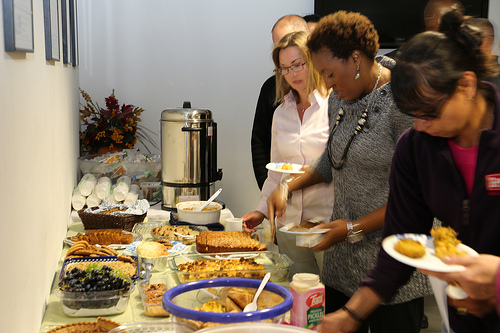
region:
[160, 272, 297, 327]
a buffet on a table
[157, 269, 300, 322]
bowl has a white spoon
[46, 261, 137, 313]
black grapes on a bowl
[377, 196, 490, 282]
a white dish with yellow food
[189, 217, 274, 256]
bread cutted in slices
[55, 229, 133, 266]
cookies behind grapes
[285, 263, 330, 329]
a bottle of souce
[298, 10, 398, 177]
woman wears a necklace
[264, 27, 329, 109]
woman wearing glasses is blonde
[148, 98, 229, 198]
a silver coffee dispenser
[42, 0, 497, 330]
people getting food at a buffet table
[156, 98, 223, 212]
coffee urn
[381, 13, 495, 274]
woman looking down with plate in hand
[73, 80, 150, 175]
flower arrangement in the corner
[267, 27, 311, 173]
blonde-haired woman with glasses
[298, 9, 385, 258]
woman wearing necklace getting some food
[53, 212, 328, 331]
variety of food on a table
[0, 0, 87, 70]
pictures on the wall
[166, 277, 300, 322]
a plastic spoon in a bowl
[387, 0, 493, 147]
woman with hair tied back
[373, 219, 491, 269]
a paper plate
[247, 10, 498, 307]
people waiting in line for food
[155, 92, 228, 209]
a silver and black drink dispenser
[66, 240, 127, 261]
a plate of cookies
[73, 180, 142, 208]
a stack of paper cups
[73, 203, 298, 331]
a table with several platters of food on it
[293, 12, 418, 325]
an african woman getting food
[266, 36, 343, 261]
a young, white woman getting food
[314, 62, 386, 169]
silver and black necklace on the african woman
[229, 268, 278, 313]
a plastic spoon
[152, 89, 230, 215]
Commercial coffee carafe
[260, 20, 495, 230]
Three women of different races dish food onto their plates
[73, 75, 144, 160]
Bouquet of autumnal colored flowers in corner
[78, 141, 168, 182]
Colorful items in clear serving bowl of ice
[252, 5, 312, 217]
Man waits for turn in food line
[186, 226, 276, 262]
Sliced and plated bread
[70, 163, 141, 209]
Cups in packs lying on their sides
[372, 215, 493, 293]
Blurry plate of food held by unknown person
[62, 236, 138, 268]
Plate of cookies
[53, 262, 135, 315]
Bowl of purple grapes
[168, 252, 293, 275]
baked casserole in a white dish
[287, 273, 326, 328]
pink container with a colorful label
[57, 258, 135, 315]
container of dark berries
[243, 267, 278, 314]
white spoon in a purple rimmed plastic container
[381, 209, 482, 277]
food on the woman's plate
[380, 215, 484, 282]
a plate of food in the woman's hand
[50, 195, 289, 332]
a variety of different foods on the table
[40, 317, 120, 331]
pie on the table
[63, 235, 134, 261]
stacks of baked cookes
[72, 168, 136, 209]
white disposable cups